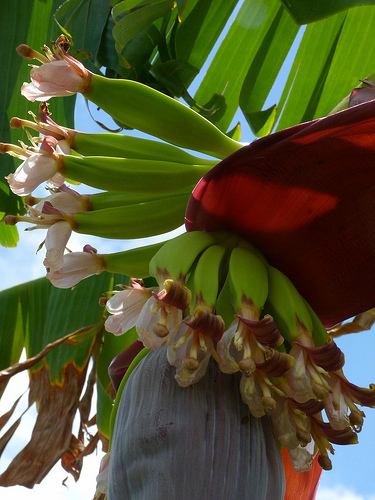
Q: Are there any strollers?
A: No, there are no strollers.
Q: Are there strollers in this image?
A: No, there are no strollers.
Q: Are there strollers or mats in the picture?
A: No, there are no strollers or mats.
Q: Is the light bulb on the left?
A: Yes, the light bulb is on the left of the image.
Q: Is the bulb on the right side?
A: No, the bulb is on the left of the image.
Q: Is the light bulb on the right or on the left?
A: The light bulb is on the left of the image.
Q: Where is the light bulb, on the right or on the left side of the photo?
A: The light bulb is on the left of the image.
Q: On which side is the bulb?
A: The bulb is on the left of the image.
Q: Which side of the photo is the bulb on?
A: The bulb is on the left of the image.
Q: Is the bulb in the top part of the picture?
A: Yes, the bulb is in the top of the image.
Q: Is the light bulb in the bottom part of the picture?
A: No, the light bulb is in the top of the image.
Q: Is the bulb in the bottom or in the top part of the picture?
A: The bulb is in the top of the image.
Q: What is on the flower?
A: The light bulb is on the flower.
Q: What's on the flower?
A: The light bulb is on the flower.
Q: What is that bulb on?
A: The bulb is on the flower.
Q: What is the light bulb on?
A: The bulb is on the flower.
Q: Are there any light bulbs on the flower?
A: Yes, there is a light bulb on the flower.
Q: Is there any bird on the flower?
A: No, there is a light bulb on the flower.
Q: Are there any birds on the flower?
A: No, there is a light bulb on the flower.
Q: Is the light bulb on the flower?
A: Yes, the light bulb is on the flower.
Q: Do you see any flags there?
A: No, there are no flags.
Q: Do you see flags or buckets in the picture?
A: No, there are no flags or buckets.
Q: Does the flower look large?
A: Yes, the flower is large.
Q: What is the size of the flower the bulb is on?
A: The flower is large.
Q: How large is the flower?
A: The flower is large.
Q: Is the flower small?
A: No, the flower is large.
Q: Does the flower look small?
A: No, the flower is large.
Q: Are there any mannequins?
A: No, there are no mannequins.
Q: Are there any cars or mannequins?
A: No, there are no mannequins or cars.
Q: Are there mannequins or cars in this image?
A: No, there are no mannequins or cars.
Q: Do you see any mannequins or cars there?
A: No, there are no mannequins or cars.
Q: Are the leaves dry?
A: Yes, the leaves are dry.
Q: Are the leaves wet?
A: No, the leaves are dry.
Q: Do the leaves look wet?
A: No, the leaves are dry.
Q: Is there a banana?
A: Yes, there is a banana.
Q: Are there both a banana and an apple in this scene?
A: No, there is a banana but no apples.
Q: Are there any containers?
A: No, there are no containers.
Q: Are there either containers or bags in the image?
A: No, there are no containers or bags.